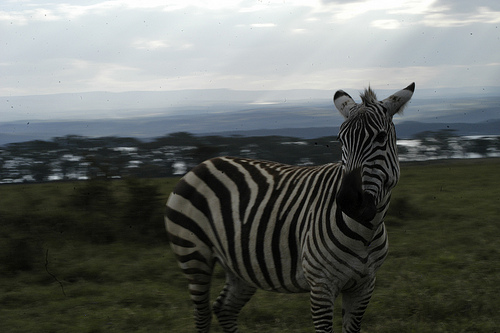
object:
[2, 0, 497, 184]
background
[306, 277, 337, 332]
leg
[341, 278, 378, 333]
leg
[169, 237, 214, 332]
leg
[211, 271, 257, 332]
leg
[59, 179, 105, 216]
tree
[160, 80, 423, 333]
zebra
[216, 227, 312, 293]
belly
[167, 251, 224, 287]
thigh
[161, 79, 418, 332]
animal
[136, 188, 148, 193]
leaves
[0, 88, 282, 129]
hill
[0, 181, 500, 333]
floor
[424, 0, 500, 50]
clouds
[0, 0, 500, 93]
sky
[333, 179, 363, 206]
nose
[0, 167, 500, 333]
grass area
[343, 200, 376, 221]
mouth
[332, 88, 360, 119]
ear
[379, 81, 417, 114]
ear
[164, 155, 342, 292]
body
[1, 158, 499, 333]
grass